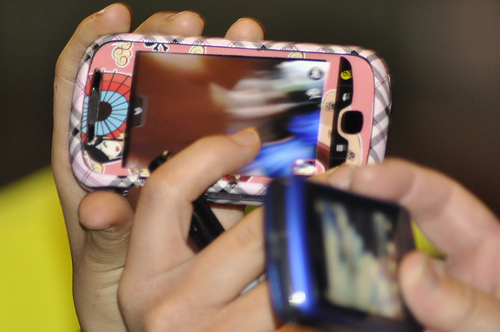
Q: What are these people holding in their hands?
A: Cell phones.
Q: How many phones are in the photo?
A: Two.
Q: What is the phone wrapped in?
A: A case.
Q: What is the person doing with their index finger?
A: Swiping the phone.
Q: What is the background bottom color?
A: Yellow.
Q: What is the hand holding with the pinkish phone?
A: An ink pen.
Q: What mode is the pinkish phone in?
A: Camera.